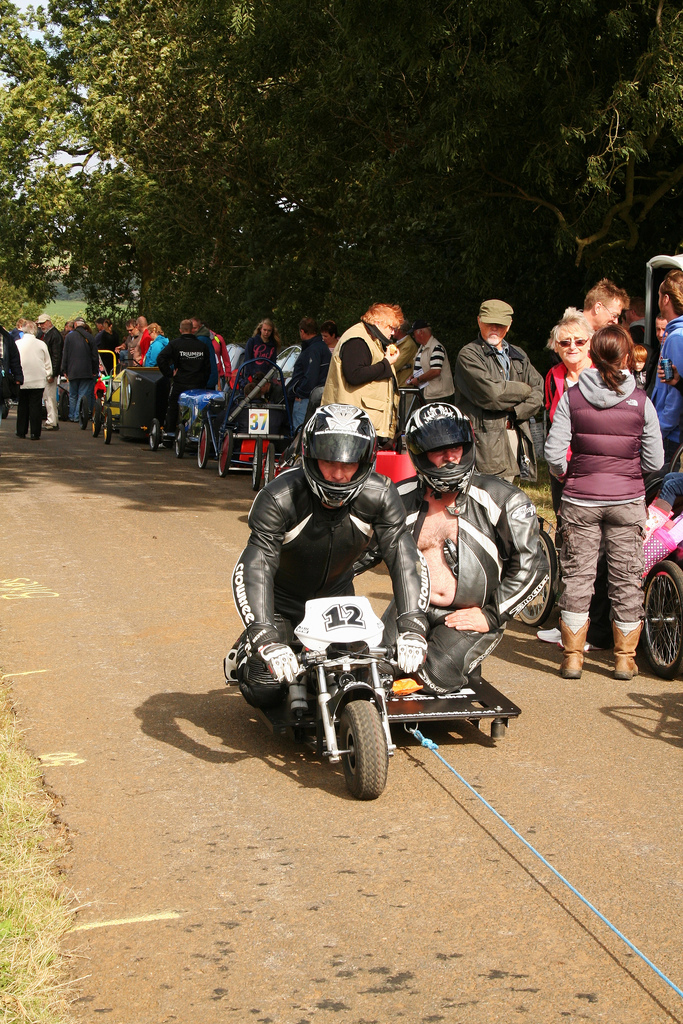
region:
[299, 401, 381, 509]
black motorcycle racing helmet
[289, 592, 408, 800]
pocket motorcycle racing bike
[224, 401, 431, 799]
man riding a pocket motorcycle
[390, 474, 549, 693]
man wearing a black leather racing jacket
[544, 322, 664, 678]
woman wearing a purple vest and brown boots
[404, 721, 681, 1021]
blue tow line attached to the pocket motorcycle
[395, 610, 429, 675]
man wearing motorcycle racing gloves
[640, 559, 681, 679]
spoke wheel of a bicycle parked on the roadside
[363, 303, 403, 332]
the hair is red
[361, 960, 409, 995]
black spots on road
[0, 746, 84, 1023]
the grass is dry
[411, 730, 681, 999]
the rope is blue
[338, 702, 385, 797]
tire of the bike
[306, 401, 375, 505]
black and white helmet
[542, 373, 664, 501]
purple and gray jacket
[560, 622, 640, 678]
the boots are brown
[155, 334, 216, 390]
the jacket is black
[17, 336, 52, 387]
the jacket is white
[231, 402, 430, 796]
Big man on a mini bike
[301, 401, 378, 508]
Black and white motorcycle helmet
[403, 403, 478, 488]
black and white motorcycle helmet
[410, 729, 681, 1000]
Light blue tow rope attached to a metal board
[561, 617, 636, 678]
Tan winter boots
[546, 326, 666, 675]
Woman wearing maroon vest over a sweater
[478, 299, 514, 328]
Khaki hat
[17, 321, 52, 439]
Older woman wearing a white jacket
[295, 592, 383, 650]
Number plate on mini bike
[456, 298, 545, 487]
Older man wearing a hat and green jacket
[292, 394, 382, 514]
Man wearing a helmet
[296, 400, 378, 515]
Man is wearing a helmet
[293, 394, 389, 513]
Man wearing a black and white helmet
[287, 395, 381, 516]
Man is wearing a black and white helmet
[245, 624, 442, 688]
Man wearing gloves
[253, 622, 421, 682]
Man is wearing gloves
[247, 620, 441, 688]
Man is wearing black and white gloves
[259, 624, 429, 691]
Man wearing black and white gloves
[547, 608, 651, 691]
Person wearing brown boots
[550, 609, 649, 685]
Person is wearing brown boots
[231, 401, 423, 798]
man driving a very small motorcycle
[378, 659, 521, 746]
short motorcycle sidecar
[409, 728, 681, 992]
blue tow cable from the side car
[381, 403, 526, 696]
man on the sidecar platform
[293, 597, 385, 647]
black number on a white panel on front of motorcycle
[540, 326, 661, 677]
woman in purple vest and cowboy boots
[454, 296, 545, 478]
man in a jacket and green hat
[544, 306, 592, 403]
older woman with sunglasses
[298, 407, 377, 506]
black and white motorcycle helmet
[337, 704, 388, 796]
front tire of the motorcycle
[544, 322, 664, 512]
The back of a woman wearing a vest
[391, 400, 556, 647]
A man wearing a black leather jacket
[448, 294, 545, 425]
A man with his arms crossed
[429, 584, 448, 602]
The bellybutton of a chubby man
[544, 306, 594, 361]
A woman with short hair wearing sunglasses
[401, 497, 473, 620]
The man is showing his fat belly.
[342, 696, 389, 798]
Tire of the scotter.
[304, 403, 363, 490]
The man is wearing a helmet.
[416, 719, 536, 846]
A blue rope pulling the cart.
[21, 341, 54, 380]
The jacket is white.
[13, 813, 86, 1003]
The grass is dry and brown.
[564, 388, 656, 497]
A purple vest on the woman.